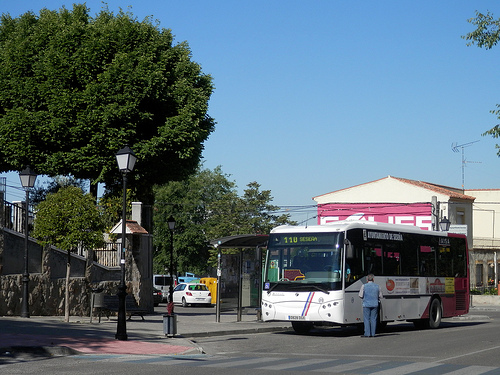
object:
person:
[358, 273, 383, 338]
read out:
[283, 235, 320, 244]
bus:
[259, 219, 470, 333]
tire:
[422, 297, 441, 329]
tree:
[0, 0, 217, 205]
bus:
[244, 216, 409, 316]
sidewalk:
[0, 314, 203, 360]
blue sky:
[0, 0, 499, 227]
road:
[4, 309, 498, 374]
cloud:
[0, 0, 499, 226]